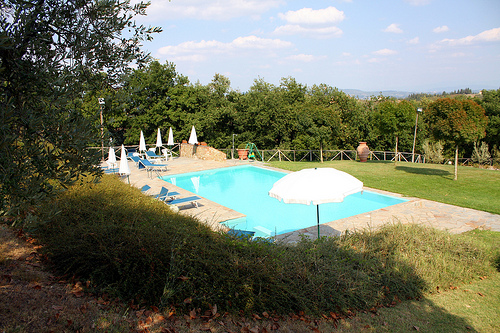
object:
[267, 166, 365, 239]
umbrella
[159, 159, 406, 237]
pool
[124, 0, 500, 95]
clouds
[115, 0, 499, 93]
sky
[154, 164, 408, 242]
water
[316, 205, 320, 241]
pole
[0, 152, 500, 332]
bushes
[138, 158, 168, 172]
chairs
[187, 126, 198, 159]
umbrellas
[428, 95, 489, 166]
trees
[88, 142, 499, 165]
fencing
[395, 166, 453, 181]
shadows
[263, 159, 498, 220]
grass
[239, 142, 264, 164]
swing set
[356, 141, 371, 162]
vase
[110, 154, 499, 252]
patio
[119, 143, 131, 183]
umbrellas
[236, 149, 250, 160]
plant pot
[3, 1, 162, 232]
tree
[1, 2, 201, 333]
side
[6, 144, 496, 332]
backyard